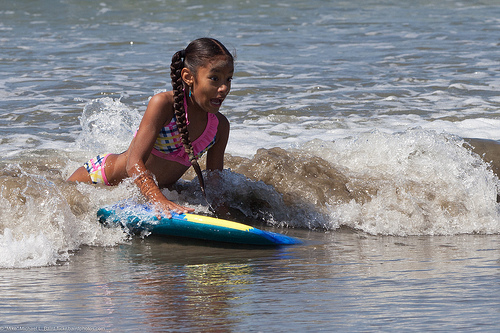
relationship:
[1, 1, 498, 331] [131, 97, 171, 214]
sea splashing on arm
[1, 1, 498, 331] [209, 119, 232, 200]
sea splashing on arm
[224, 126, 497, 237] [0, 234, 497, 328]
wave crashing on shore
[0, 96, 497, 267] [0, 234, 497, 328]
wave crashing on shore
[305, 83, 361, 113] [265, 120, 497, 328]
foam in water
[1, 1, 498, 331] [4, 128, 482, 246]
sea in front wave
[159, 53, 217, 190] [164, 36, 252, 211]
braid in hair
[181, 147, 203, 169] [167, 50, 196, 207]
rubberband ties braid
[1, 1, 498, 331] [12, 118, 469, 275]
sea behind wave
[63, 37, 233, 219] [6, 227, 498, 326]
girl playing beach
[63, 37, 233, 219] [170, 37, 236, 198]
girl has hair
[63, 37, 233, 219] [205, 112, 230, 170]
girl has arm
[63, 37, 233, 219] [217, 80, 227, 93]
girl has nose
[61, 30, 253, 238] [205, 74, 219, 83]
girl has eye